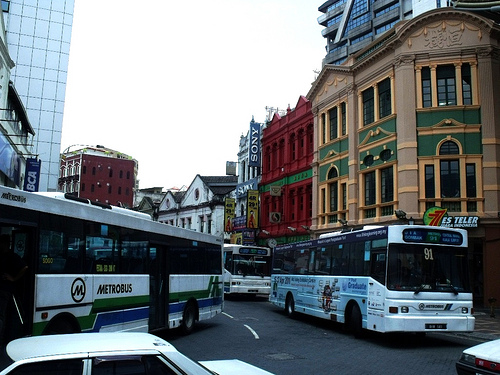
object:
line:
[244, 324, 259, 338]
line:
[221, 311, 233, 319]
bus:
[269, 224, 476, 334]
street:
[167, 299, 472, 374]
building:
[259, 94, 313, 248]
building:
[306, 7, 498, 309]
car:
[0, 332, 277, 374]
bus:
[0, 183, 224, 340]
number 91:
[424, 248, 434, 260]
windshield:
[387, 242, 472, 292]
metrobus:
[97, 283, 132, 294]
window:
[83, 166, 87, 174]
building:
[60, 144, 138, 206]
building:
[2, 0, 77, 192]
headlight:
[401, 306, 409, 313]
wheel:
[285, 291, 294, 319]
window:
[415, 59, 478, 109]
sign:
[249, 123, 261, 166]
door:
[149, 243, 169, 333]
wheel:
[347, 302, 362, 338]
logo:
[71, 277, 86, 302]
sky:
[64, 0, 297, 183]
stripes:
[78, 295, 150, 333]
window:
[48, 22, 64, 41]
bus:
[223, 244, 271, 298]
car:
[454, 339, 499, 374]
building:
[316, 0, 413, 66]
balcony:
[317, 5, 345, 24]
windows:
[360, 19, 365, 25]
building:
[158, 174, 239, 234]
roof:
[177, 174, 241, 208]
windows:
[272, 242, 364, 277]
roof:
[7, 331, 164, 358]